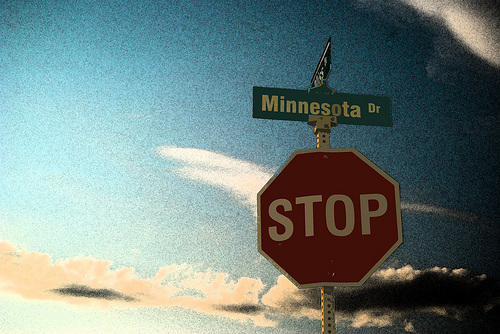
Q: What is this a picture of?
A: A stop sign.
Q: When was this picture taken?
A: Daytime.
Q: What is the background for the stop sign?
A: The sky.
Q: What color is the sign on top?
A: Green and white.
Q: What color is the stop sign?
A: Red and white.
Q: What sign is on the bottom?
A: The stop sign.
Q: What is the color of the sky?
A: Blue.